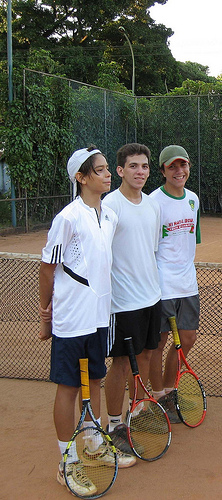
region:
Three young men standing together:
[38, 135, 204, 283]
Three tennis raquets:
[56, 314, 208, 497]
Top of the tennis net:
[2, 246, 36, 317]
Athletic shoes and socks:
[52, 415, 136, 496]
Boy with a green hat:
[158, 142, 192, 187]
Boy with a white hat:
[63, 145, 114, 205]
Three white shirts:
[35, 183, 204, 340]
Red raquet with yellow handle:
[165, 313, 208, 431]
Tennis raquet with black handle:
[120, 334, 173, 463]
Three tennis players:
[37, 137, 210, 497]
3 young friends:
[36, 111, 220, 268]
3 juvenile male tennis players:
[38, 115, 210, 465]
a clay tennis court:
[8, 330, 53, 445]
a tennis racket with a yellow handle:
[55, 355, 86, 485]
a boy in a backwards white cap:
[60, 138, 118, 204]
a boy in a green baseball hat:
[161, 145, 202, 221]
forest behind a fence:
[32, 53, 208, 136]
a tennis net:
[6, 240, 37, 307]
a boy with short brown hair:
[114, 138, 151, 209]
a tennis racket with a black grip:
[117, 329, 180, 456]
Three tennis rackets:
[40, 314, 207, 499]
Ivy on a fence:
[0, 59, 66, 206]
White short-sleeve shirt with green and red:
[149, 187, 203, 294]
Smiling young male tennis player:
[156, 141, 206, 423]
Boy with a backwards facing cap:
[64, 143, 113, 205]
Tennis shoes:
[44, 386, 205, 499]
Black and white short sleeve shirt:
[36, 196, 120, 337]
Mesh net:
[0, 247, 220, 398]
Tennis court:
[0, 214, 220, 499]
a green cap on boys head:
[157, 145, 189, 168]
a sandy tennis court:
[167, 468, 214, 491]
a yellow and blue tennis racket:
[62, 355, 120, 498]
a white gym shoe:
[56, 459, 98, 497]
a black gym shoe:
[102, 421, 144, 456]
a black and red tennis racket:
[122, 336, 171, 461]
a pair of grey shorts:
[158, 294, 201, 331]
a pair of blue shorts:
[49, 324, 110, 388]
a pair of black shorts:
[108, 299, 161, 356]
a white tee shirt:
[100, 186, 162, 314]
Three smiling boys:
[31, 140, 211, 301]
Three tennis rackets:
[59, 320, 213, 496]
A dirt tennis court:
[2, 237, 217, 497]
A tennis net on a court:
[2, 250, 221, 377]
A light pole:
[110, 24, 142, 129]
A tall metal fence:
[22, 69, 221, 208]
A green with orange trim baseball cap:
[156, 146, 197, 206]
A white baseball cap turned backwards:
[57, 143, 115, 205]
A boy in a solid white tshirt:
[111, 145, 160, 308]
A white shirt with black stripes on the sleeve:
[41, 150, 119, 336]